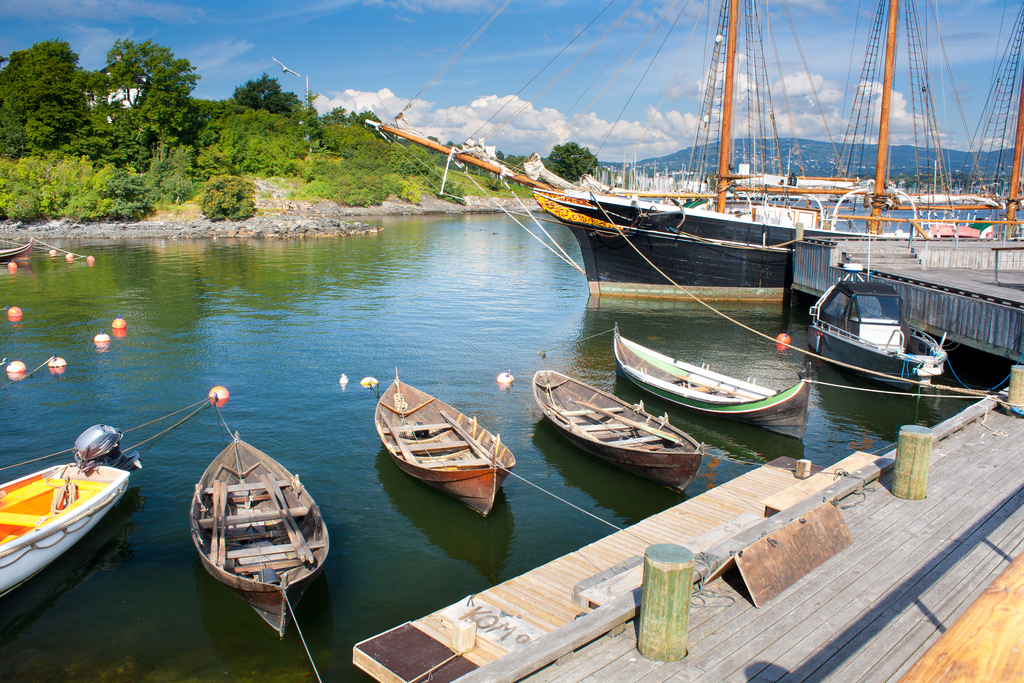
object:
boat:
[360, 0, 1023, 312]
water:
[269, 246, 411, 362]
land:
[186, 92, 318, 159]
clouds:
[443, 83, 542, 137]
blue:
[364, 25, 419, 53]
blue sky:
[0, 0, 1023, 136]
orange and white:
[775, 332, 792, 350]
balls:
[774, 331, 794, 352]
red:
[455, 470, 491, 492]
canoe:
[373, 364, 519, 519]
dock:
[785, 235, 1024, 368]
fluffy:
[393, 99, 699, 144]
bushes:
[147, 101, 294, 184]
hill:
[164, 116, 399, 225]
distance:
[747, 116, 1023, 178]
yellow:
[555, 199, 568, 218]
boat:
[0, 462, 132, 600]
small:
[805, 252, 953, 392]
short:
[889, 423, 935, 501]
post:
[866, 0, 899, 237]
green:
[715, 405, 742, 411]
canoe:
[532, 368, 706, 493]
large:
[354, 0, 1023, 313]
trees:
[0, 36, 115, 162]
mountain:
[654, 127, 949, 188]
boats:
[188, 429, 333, 639]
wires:
[391, 0, 515, 124]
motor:
[854, 338, 947, 388]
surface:
[280, 207, 515, 329]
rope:
[595, 198, 998, 401]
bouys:
[495, 368, 516, 389]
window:
[855, 294, 900, 320]